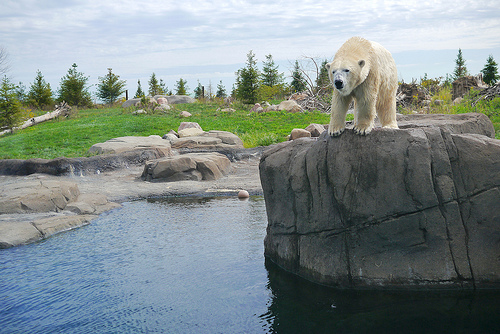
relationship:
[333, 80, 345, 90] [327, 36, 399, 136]
nose of polar bear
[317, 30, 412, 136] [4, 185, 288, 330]
bear in pond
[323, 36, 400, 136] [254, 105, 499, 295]
bear in rock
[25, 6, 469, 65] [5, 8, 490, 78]
clouds in sky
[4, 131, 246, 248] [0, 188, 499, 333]
rocks in pond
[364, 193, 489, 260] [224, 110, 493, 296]
cracks in rock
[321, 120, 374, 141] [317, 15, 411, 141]
paws of bear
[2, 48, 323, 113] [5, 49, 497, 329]
trees in enclosure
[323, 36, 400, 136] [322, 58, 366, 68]
bear has ears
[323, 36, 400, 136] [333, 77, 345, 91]
bear has nose